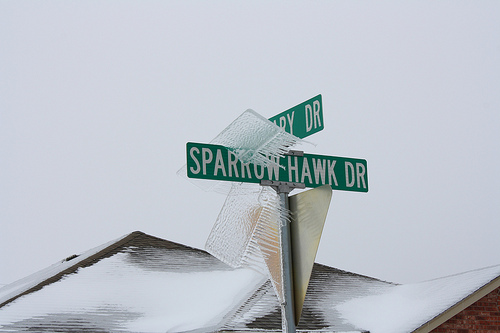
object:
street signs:
[267, 94, 324, 140]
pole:
[277, 193, 297, 333]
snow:
[162, 282, 211, 302]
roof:
[0, 229, 140, 305]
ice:
[227, 111, 301, 156]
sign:
[246, 184, 332, 326]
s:
[190, 146, 201, 174]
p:
[202, 147, 214, 175]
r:
[228, 150, 239, 177]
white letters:
[305, 104, 312, 132]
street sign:
[174, 132, 370, 193]